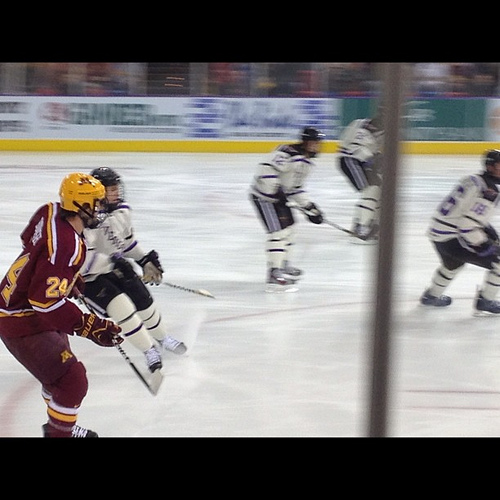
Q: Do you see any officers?
A: No, there are no officers.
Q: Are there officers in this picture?
A: No, there are no officers.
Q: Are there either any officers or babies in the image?
A: No, there are no officers or babies.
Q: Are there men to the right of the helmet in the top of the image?
A: Yes, there are men to the right of the helmet.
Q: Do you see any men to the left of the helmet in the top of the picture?
A: No, the men are to the right of the helmet.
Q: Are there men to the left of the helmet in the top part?
A: No, the men are to the right of the helmet.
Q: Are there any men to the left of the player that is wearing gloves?
A: Yes, there are men to the left of the player.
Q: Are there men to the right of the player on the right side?
A: No, the men are to the left of the player.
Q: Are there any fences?
A: No, there are no fences.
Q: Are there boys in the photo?
A: No, there are no boys.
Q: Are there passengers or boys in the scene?
A: No, there are no boys or passengers.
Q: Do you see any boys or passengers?
A: No, there are no boys or passengers.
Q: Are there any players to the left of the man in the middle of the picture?
A: Yes, there are players to the left of the man.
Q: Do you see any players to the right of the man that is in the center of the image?
A: No, the players are to the left of the man.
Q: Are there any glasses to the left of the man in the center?
A: No, there are players to the left of the man.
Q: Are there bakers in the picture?
A: No, there are no bakers.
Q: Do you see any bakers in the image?
A: No, there are no bakers.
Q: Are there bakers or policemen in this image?
A: No, there are no bakers or policemen.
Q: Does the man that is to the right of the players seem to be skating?
A: Yes, the man is skating.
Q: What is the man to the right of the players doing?
A: The man is skating.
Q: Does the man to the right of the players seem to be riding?
A: No, the man is skating.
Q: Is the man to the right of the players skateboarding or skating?
A: The man is skating.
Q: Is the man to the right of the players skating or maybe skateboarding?
A: The man is skating.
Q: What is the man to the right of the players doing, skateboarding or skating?
A: The man is skating.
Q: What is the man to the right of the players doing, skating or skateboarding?
A: The man is skating.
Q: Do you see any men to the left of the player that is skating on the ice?
A: Yes, there is a man to the left of the player.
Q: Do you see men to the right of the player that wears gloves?
A: No, the man is to the left of the player.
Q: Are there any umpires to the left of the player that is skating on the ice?
A: No, there is a man to the left of the player.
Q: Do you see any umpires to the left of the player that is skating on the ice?
A: No, there is a man to the left of the player.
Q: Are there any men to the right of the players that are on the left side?
A: Yes, there is a man to the right of the players.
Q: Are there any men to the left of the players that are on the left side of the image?
A: No, the man is to the right of the players.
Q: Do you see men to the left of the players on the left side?
A: No, the man is to the right of the players.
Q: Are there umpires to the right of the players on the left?
A: No, there is a man to the right of the players.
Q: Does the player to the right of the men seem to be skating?
A: Yes, the player is skating.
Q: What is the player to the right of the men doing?
A: The player is skating.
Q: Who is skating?
A: The player is skating.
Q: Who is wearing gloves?
A: The player is wearing gloves.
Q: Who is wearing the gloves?
A: The player is wearing gloves.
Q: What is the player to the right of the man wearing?
A: The player is wearing gloves.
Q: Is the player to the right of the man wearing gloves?
A: Yes, the player is wearing gloves.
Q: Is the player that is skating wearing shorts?
A: No, the player is wearing gloves.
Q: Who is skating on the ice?
A: The player is skating on the ice.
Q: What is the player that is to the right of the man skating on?
A: The player is skating on the ice.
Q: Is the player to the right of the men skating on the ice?
A: Yes, the player is skating on the ice.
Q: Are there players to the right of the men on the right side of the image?
A: Yes, there is a player to the right of the men.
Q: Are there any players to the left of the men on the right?
A: No, the player is to the right of the men.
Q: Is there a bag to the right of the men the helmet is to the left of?
A: No, there is a player to the right of the men.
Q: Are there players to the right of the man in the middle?
A: Yes, there is a player to the right of the man.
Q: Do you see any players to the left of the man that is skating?
A: No, the player is to the right of the man.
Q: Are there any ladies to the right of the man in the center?
A: No, there is a player to the right of the man.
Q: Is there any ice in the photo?
A: Yes, there is ice.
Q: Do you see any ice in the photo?
A: Yes, there is ice.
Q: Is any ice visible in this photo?
A: Yes, there is ice.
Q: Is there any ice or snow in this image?
A: Yes, there is ice.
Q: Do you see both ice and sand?
A: No, there is ice but no sand.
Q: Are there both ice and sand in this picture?
A: No, there is ice but no sand.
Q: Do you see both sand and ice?
A: No, there is ice but no sand.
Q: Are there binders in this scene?
A: No, there are no binders.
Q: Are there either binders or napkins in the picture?
A: No, there are no binders or napkins.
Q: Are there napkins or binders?
A: No, there are no binders or napkins.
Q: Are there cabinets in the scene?
A: No, there are no cabinets.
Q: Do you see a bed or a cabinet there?
A: No, there are no cabinets or beds.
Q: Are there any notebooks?
A: No, there are no notebooks.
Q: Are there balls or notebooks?
A: No, there are no notebooks or balls.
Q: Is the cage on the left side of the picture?
A: Yes, the cage is on the left of the image.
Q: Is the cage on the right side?
A: No, the cage is on the left of the image.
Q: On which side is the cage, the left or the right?
A: The cage is on the left of the image.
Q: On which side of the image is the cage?
A: The cage is on the left of the image.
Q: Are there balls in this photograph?
A: No, there are no balls.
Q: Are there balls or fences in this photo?
A: No, there are no balls or fences.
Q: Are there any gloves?
A: Yes, there are gloves.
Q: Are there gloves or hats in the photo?
A: Yes, there are gloves.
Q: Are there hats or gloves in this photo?
A: Yes, there are gloves.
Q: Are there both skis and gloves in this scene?
A: No, there are gloves but no skis.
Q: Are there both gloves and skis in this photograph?
A: No, there are gloves but no skis.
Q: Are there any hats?
A: No, there are no hats.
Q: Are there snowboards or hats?
A: No, there are no hats or snowboards.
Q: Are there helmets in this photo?
A: Yes, there is a helmet.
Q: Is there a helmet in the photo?
A: Yes, there is a helmet.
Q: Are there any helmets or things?
A: Yes, there is a helmet.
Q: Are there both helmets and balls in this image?
A: No, there is a helmet but no balls.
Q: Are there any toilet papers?
A: No, there are no toilet papers.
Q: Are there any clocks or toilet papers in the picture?
A: No, there are no toilet papers or clocks.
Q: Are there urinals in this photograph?
A: No, there are no urinals.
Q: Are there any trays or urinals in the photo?
A: No, there are no urinals or trays.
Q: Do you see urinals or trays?
A: No, there are no urinals or trays.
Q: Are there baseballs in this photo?
A: No, there are no baseballs.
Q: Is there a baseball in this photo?
A: No, there are no baseballs.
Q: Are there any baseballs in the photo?
A: No, there are no baseballs.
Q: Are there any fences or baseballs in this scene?
A: No, there are no baseballs or fences.